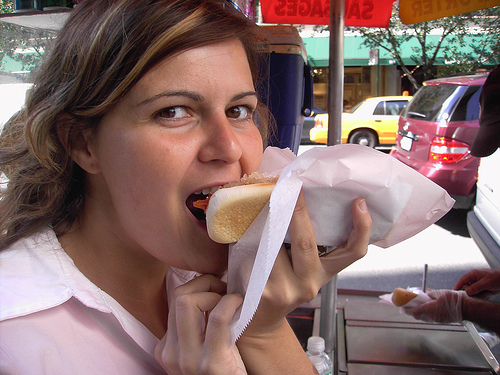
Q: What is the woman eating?
A: Hot dog.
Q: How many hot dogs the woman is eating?
A: One.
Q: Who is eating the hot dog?
A: The woman.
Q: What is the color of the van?
A: Red.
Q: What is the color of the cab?
A: Yellow.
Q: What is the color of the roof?
A: Green.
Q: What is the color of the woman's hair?
A: Brown.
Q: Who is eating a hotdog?
A: A woman.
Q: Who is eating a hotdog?
A: A woman.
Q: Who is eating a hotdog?
A: A woman.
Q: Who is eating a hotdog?
A: A woman.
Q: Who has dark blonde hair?
A: Happy woman.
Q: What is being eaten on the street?
A: Paper wrapped hotdog.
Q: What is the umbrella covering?
A: A vendor's cart.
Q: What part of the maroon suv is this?
A: Back end.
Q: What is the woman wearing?
A: Pink collared button down shirt.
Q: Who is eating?
A: A woman.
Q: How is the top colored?
A: Pink.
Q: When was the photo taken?
A: Daytime.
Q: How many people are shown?
A: One.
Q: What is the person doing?
A: Eating.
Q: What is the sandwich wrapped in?
A: Paper.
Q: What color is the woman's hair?
A: Brown.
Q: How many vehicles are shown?
A: Two.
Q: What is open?
A: Woman's mouth.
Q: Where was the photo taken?
A: In a restaurant.